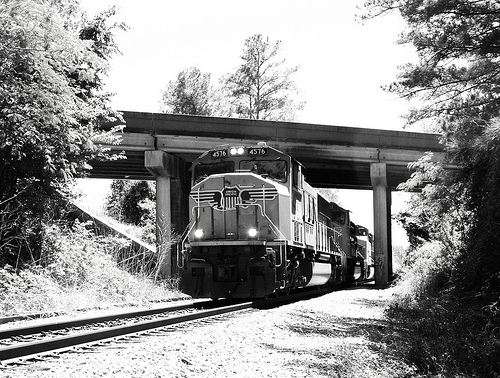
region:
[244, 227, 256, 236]
The right headlight on the train.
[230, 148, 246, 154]
The center lights on the train.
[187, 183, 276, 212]
The emblem on the train.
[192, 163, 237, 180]
The left window of the train.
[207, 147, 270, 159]
The numbers 4576 on the train.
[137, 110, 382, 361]
this is a train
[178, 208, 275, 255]
lights on the train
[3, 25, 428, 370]
train on the tracks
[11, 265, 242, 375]
a set of train tracks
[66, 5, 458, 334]
train under a bridge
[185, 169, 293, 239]
this is a union pacific train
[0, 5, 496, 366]
trees surround train tracks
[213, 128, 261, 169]
lights on the top of train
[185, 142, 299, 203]
front two windows on train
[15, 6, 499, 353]
a bright and clear day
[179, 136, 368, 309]
Large train on the tracks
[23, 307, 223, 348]
Train tracks on the gorund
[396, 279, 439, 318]
Small leaves on a tree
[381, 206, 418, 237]
Small leaves on a tree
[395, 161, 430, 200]
Small leaves on a tree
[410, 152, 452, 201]
Small leaves on a tree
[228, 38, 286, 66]
Small leaves on a tree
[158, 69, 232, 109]
Small leaves on a tree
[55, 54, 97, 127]
Small leaves on a tree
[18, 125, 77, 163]
Small leaves on a tree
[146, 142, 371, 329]
a train on a train track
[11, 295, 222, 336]
a set of train tracks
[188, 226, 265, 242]
headlights on a train car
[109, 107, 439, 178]
a concrete bridge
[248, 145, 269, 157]
numbers on a train car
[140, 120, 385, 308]
a train under a bridge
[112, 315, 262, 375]
gravel next to a train track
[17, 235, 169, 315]
tall weeds and brush next to a train track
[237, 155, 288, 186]
windshield on a train car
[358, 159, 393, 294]
a concrete column for a bridge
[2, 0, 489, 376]
a black and white image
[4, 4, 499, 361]
a scene during the day time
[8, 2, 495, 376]
a scene outside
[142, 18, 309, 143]
a couple of trees in the background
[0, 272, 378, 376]
a train track on the ground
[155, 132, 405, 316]
a train on a track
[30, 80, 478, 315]
a bridge over the train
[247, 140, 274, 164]
4576 on train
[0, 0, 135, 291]
a tree on the left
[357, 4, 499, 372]
a tree on the right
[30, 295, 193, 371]
a set of train tracks